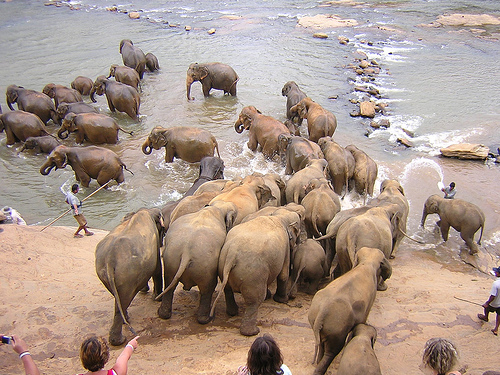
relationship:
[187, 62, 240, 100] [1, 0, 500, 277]
elephant in water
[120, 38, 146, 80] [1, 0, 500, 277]
elephant in water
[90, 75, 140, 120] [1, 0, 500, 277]
elephant in water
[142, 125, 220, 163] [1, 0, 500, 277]
elephant in water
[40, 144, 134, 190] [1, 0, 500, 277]
elephant in water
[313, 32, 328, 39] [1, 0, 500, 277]
rock in water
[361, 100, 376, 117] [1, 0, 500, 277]
rock in water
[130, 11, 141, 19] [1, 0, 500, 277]
rock in water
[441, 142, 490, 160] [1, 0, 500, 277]
rock in water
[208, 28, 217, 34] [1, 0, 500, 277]
rock in water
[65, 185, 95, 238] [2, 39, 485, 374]
man herding elephants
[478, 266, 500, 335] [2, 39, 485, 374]
man herding elephants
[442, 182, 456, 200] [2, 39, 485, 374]
man herding elephants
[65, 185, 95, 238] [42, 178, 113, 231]
man has stick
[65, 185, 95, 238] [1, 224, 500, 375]
man on bank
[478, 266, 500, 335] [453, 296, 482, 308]
man has stick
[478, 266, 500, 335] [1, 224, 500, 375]
man on bank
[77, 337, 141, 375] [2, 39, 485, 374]
woman pointing toward elephants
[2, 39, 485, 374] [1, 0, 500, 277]
elephants walking toward water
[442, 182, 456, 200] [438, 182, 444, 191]
man throwing bucket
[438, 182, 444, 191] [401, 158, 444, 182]
bucket has water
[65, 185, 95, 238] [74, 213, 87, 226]
man wearing shorts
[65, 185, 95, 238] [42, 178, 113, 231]
man holding stick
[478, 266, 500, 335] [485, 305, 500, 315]
man wearing shorts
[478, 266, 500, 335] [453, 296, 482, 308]
man holding stick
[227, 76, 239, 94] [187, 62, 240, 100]
tail on elephant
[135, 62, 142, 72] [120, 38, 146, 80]
tail on elephant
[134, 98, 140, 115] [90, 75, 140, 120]
tail on elephant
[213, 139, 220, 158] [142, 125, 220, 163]
tail on elephant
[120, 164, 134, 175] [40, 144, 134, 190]
tail on elephant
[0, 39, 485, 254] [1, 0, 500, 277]
elephants walking in water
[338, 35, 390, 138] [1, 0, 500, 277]
rocks in water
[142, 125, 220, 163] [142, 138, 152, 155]
elephant has trunk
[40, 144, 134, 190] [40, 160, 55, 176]
elephant has trunk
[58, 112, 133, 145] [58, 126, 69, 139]
elephant has trunk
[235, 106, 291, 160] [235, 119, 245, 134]
elephant has trunk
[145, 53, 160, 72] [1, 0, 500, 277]
elephant in water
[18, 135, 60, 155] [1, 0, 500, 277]
elephant in water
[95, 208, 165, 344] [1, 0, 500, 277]
elephant walking toward water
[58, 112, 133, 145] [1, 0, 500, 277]
elephant in water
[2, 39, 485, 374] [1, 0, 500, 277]
elephants herding through water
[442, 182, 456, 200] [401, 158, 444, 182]
man tossing water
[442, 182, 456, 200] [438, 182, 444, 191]
man using bucket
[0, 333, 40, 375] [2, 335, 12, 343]
person using camera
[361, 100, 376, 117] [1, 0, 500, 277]
rock not under water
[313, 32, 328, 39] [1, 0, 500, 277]
rock not under water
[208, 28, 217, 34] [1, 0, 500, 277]
rock not under water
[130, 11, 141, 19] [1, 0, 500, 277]
rock not under water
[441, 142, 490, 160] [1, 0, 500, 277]
rock not under water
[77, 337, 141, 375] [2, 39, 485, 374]
woman pointing at elephants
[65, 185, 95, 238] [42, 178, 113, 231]
man with stick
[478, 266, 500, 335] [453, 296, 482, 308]
man with stick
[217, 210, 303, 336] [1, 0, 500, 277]
elephant trying to get in water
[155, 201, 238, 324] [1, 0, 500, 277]
elephant trying to get in water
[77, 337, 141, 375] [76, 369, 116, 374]
woman wearing shirt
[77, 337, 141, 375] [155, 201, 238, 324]
woman pointing at elephant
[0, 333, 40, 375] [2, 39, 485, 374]
person taking picture of elephants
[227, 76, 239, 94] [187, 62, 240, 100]
tail of elephant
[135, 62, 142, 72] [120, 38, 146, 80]
tail of elephant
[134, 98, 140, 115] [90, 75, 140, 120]
tail of elephant